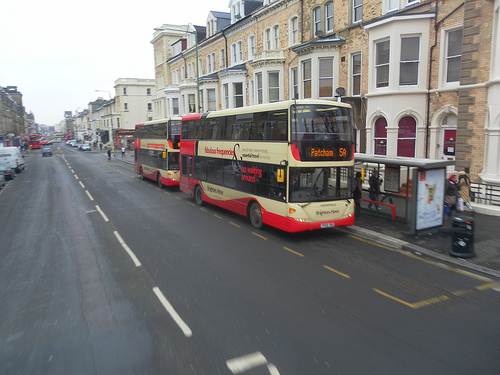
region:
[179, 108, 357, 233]
Red and white double decker bus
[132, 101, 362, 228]
Two double decker buses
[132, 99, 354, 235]
Two red and white buses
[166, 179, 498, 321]
Yellow marks on road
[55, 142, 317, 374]
White lines on road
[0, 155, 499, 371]
A gray tarmacked road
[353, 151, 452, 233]
White shade beside road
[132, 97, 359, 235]
Two buses at the bus stop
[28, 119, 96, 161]
Cars moving on the road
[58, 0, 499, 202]
Buildings along the road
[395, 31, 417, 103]
Large window on a building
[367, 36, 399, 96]
Large window on a building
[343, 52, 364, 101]
Large window on a building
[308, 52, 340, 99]
Large window on a building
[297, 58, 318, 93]
Large window on a building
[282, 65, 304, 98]
Large window on a building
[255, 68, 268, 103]
Large window on a building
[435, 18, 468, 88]
Large window on a building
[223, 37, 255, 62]
Large window on a building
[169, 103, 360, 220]
a double decker bus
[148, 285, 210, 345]
a white line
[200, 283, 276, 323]
the street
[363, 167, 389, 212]
a person standing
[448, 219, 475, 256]
a trash can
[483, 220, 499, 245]
the sidewalk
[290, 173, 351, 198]
the windshield on the bus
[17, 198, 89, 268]
the street is black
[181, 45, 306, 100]
a building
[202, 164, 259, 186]
windows on the bus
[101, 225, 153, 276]
white line painted on pavement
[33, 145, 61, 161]
vehicle driving on road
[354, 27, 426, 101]
windows on side of building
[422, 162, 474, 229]
people walking on sidewalk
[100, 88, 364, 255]
two stopped double decker buses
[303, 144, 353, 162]
writing on front of double decker bus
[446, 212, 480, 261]
black metal trash can on sidewalk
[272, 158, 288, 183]
yellow metal side mirror on bus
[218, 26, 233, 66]
black metal gutter on side of house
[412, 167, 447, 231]
advertisement on side of bus stop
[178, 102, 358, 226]
a double decker bus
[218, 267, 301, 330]
the street is black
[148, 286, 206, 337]
white line in the street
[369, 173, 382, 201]
a person standing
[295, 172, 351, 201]
windshield on the bus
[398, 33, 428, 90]
windows on the building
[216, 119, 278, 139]
windows on the bus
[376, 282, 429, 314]
a line that is yellow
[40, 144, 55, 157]
a car in the street